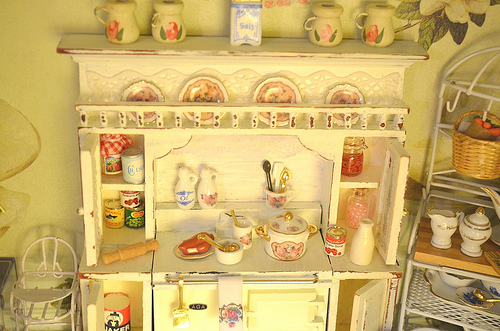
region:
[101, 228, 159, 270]
a toy rolling pin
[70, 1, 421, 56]
countertop with white vases on it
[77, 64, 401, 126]
childrens toy fine china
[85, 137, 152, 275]
toy cabinet with fake food in it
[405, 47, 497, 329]
white wire shelf with items on it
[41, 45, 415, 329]
this is a kitchen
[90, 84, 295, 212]
the cabinet is white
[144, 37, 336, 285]
the cabinet is wooden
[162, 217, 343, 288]
this is cooking stuff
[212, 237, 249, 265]
the bowl is white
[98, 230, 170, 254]
this is a rolling pin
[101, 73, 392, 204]
the cabinet is fancy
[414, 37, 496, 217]
the shelves are metal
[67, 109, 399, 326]
a shelf with stuff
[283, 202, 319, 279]
a pot on table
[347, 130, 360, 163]
jar on table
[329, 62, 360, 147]
plate on a table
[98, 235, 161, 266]
beige wooden rolling pin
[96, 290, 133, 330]
blue red and white cylindrical box of oatmeal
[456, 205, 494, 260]
white and gold porcelain sugar container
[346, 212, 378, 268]
small white milk pitcher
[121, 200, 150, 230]
green metal can of vegetables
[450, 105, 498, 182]
tan wicker basket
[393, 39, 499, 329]
white metal shelf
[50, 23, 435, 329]
light yellow stove and cabinet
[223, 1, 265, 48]
white and blue salt container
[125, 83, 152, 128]
a plate on a shelf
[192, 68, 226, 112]
a plate on a shelf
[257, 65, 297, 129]
a plate on a shelf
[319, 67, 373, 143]
a plate on a shelf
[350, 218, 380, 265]
a vase on a table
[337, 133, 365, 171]
a jar on a shelf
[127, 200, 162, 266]
a can on a shelf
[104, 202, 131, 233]
a can on a shelf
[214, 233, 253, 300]
a bowl on a plate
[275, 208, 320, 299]
a pot on a plate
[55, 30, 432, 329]
a miniature doll house cupboard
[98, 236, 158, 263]
a miniature rolling pin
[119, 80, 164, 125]
a miniature decorative plate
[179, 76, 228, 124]
a miniature decorative plate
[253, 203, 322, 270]
a white china piece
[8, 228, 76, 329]
a white iron chair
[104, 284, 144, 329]
a old oatmeal box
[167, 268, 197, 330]
a gold paint brush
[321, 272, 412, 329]
the door is open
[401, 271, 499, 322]
a platter of fine china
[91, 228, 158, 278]
a wood rolling pen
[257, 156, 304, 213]
spoons in a cup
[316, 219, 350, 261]
a red and white can